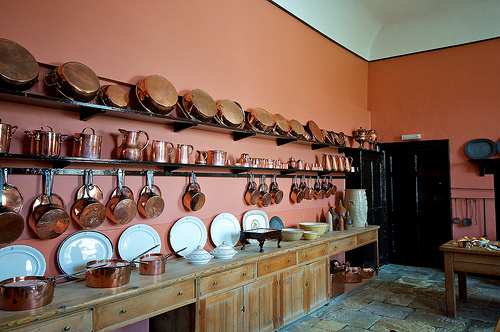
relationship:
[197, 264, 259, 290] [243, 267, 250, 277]
drawer has handle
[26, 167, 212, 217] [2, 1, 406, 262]
pans hanging from wall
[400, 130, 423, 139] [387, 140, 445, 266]
fixture above door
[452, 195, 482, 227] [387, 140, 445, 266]
soup ladel next to door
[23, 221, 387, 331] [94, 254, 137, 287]
table has pots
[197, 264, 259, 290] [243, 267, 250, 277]
drawer with handle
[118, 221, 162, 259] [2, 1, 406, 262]
plate standing against wall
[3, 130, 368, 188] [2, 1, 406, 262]
shelf on wall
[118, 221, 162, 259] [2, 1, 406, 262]
plate against wall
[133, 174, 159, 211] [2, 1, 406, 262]
pot on wall